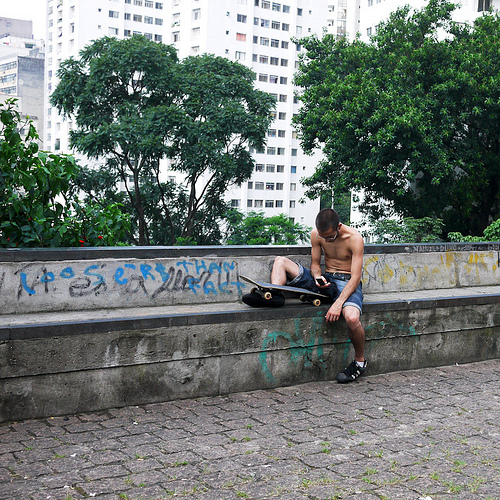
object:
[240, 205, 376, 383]
man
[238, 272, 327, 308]
skateboard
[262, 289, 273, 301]
wheel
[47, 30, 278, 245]
tree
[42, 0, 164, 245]
buildings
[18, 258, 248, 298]
grafitti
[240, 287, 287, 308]
shoe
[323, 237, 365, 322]
arm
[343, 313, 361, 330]
knee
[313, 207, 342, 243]
head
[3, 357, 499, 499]
ground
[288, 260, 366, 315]
shorts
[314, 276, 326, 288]
phone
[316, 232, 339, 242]
glasses